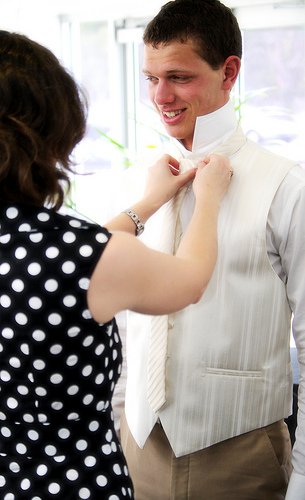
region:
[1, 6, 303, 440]
a woman tying a man's tie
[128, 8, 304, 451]
a smiling young man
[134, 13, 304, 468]
a young man getting dressed for a wedding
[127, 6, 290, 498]
a man getting dressed for a formal occasion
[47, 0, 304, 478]
a young man getting dressed for a fancy occasion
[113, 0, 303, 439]
a man dressed in a white shirt, vest, and tie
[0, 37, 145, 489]
a woman wearing a polka-dotted dress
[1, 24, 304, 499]
a woman tying her son's tie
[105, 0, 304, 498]
a man who can't tie a tie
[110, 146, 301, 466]
a matching vest and tie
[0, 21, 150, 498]
woman wearing black dress with white dots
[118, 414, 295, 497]
khaki pants of man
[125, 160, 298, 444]
white vest with stripes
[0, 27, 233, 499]
woman fixing man's tie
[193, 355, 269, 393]
pocket on white vest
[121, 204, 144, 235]
silver watch on woman's arm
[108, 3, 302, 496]
man wearing white vest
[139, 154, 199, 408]
white necktie of man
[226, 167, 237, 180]
ring on woman's finger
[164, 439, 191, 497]
zipper fly on man's pants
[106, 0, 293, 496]
this is a man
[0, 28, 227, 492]
this is a woman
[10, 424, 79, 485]
white dots on black dress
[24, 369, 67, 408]
white dots on black dress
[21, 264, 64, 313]
white dots on black dress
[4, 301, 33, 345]
white dots on black dress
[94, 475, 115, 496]
white dots on black dress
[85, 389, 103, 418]
white dots on black dress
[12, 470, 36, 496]
white dots on black dress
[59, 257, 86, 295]
white dots on black dress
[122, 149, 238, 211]
The lady is tying the tie.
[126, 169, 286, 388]
The man is wearing a white vest.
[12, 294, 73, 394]
The lady is wearing a polka dot dress.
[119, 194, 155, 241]
The lady is wearing a watch.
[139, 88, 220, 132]
The man is smiling.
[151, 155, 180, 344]
The boy is wearing a tie.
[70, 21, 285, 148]
Sunlight coming through the window.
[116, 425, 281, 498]
The man pants is beige.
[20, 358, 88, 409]
The polka dots are white.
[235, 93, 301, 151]
A car is parked outside the window.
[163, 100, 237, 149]
a white popped collar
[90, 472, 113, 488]
a single white polkadot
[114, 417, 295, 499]
a pair of tan dress pants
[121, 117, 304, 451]
a pinstripped white dress shirt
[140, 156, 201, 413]
a white skinny tie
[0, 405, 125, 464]
a white and black polkdotted belt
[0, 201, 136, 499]
a short sleeved polka dotted dress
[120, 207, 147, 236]
a woman's silver wrist watch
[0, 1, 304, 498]
A woman tieing a mans tie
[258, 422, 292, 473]
the pocket of a tan pair of pants